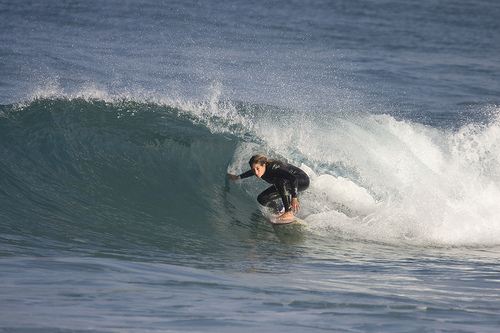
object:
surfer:
[226, 154, 310, 220]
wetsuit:
[238, 162, 310, 213]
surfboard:
[264, 208, 308, 225]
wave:
[0, 89, 500, 247]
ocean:
[0, 0, 499, 333]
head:
[249, 154, 268, 178]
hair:
[249, 154, 287, 165]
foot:
[278, 213, 295, 219]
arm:
[280, 168, 298, 199]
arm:
[240, 170, 254, 179]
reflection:
[249, 214, 306, 262]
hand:
[288, 199, 302, 213]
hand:
[227, 173, 236, 181]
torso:
[228, 155, 310, 220]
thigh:
[283, 177, 304, 190]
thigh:
[264, 185, 282, 199]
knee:
[274, 178, 292, 187]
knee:
[257, 194, 268, 205]